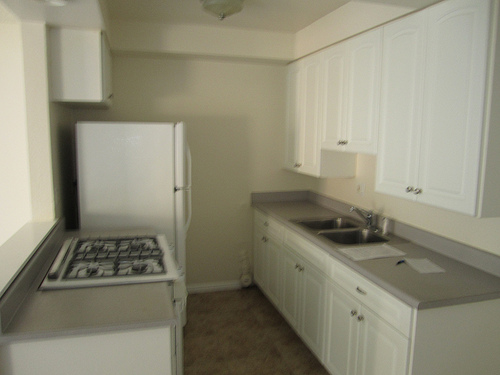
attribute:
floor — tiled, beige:
[176, 279, 335, 374]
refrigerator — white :
[72, 109, 204, 336]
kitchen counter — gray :
[251, 184, 499, 304]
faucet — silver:
[350, 205, 375, 234]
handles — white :
[180, 139, 202, 244]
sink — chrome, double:
[291, 205, 395, 245]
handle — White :
[181, 141, 196, 232]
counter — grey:
[241, 168, 497, 322]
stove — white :
[46, 217, 188, 315]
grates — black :
[74, 233, 169, 280]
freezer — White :
[75, 120, 188, 270]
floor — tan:
[208, 303, 300, 371]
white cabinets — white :
[290, 53, 444, 147]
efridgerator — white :
[80, 112, 202, 261]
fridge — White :
[73, 119, 192, 326]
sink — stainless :
[285, 197, 399, 249]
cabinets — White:
[281, 0, 496, 216]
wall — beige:
[69, 53, 287, 292]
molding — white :
[184, 280, 246, 295]